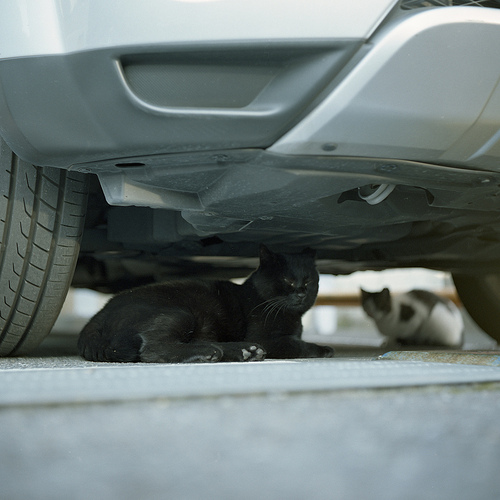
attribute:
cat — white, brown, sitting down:
[344, 268, 463, 354]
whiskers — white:
[252, 293, 290, 325]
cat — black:
[71, 241, 336, 360]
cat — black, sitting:
[49, 237, 338, 367]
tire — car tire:
[1, 150, 76, 356]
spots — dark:
[397, 307, 422, 324]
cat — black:
[71, 212, 350, 372]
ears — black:
[248, 226, 325, 283]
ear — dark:
[253, 240, 273, 262]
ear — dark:
[297, 245, 321, 262]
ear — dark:
[358, 286, 370, 298]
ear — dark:
[380, 285, 392, 298]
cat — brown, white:
[354, 283, 472, 355]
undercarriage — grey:
[113, 160, 482, 255]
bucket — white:
[315, 305, 345, 345]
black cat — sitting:
[78, 239, 333, 359]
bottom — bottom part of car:
[119, 148, 496, 265]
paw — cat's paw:
[234, 338, 269, 361]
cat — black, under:
[69, 250, 325, 365]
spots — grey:
[393, 304, 420, 326]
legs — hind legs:
[144, 332, 336, 368]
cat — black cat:
[66, 233, 343, 361]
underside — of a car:
[82, 160, 499, 243]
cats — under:
[61, 227, 481, 380]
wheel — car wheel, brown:
[2, 146, 96, 341]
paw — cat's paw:
[239, 342, 266, 362]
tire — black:
[0, 139, 90, 357]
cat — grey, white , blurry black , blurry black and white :
[358, 285, 465, 350]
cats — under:
[69, 233, 473, 365]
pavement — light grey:
[2, 284, 493, 498]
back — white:
[386, 277, 459, 364]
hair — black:
[73, 236, 390, 386]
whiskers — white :
[243, 290, 303, 335]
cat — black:
[49, 197, 331, 388]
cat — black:
[74, 220, 352, 420]